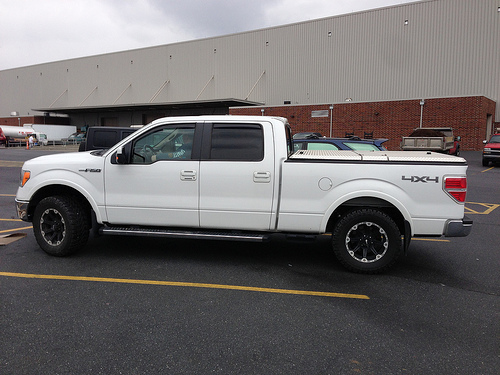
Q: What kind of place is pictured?
A: It is a road.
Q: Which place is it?
A: It is a road.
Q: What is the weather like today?
A: It is cloudy.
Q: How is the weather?
A: It is cloudy.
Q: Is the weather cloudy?
A: Yes, it is cloudy.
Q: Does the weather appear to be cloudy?
A: Yes, it is cloudy.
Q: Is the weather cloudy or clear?
A: It is cloudy.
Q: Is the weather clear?
A: No, it is cloudy.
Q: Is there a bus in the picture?
A: No, there are no buses.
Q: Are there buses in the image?
A: No, there are no buses.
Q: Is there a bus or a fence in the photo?
A: No, there are no buses or fences.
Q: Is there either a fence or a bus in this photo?
A: No, there are no buses or fences.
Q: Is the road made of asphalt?
A: Yes, the road is made of asphalt.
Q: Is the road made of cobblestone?
A: No, the road is made of asphalt.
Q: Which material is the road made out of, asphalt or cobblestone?
A: The road is made of asphalt.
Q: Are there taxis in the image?
A: Yes, there is a taxi.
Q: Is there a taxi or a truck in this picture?
A: Yes, there is a taxi.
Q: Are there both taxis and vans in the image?
A: No, there is a taxi but no vans.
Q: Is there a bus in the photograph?
A: No, there are no buses.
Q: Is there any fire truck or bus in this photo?
A: No, there are no buses or fire trucks.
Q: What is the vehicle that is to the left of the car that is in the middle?
A: The vehicle is a taxi.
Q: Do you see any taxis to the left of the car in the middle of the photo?
A: Yes, there is a taxi to the left of the car.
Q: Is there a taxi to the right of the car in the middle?
A: No, the taxi is to the left of the car.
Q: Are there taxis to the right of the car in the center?
A: No, the taxi is to the left of the car.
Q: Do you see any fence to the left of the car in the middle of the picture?
A: No, there is a taxi to the left of the car.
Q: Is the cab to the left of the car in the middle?
A: Yes, the cab is to the left of the car.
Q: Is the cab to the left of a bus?
A: No, the cab is to the left of the car.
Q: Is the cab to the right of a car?
A: No, the cab is to the left of a car.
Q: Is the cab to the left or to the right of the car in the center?
A: The cab is to the left of the car.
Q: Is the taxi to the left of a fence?
A: No, the taxi is to the left of the car.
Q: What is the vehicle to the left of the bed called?
A: The vehicle is a taxi.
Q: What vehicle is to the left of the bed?
A: The vehicle is a taxi.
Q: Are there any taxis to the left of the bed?
A: Yes, there is a taxi to the left of the bed.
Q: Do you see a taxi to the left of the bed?
A: Yes, there is a taxi to the left of the bed.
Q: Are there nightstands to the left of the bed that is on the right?
A: No, there is a taxi to the left of the bed.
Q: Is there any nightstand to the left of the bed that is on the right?
A: No, there is a taxi to the left of the bed.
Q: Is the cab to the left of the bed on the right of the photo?
A: Yes, the cab is to the left of the bed.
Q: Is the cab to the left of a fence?
A: No, the cab is to the left of the bed.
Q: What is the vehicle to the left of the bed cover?
A: The vehicle is a taxi.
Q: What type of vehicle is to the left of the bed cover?
A: The vehicle is a taxi.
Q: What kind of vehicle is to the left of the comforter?
A: The vehicle is a taxi.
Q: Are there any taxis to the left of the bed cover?
A: Yes, there is a taxi to the left of the bed cover.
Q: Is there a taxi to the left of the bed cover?
A: Yes, there is a taxi to the left of the bed cover.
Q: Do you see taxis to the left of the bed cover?
A: Yes, there is a taxi to the left of the bed cover.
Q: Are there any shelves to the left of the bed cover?
A: No, there is a taxi to the left of the bed cover.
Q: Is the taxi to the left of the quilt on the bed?
A: Yes, the taxi is to the left of the comforter.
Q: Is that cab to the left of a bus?
A: No, the cab is to the left of the comforter.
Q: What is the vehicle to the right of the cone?
A: The vehicle is a taxi.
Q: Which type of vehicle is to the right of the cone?
A: The vehicle is a taxi.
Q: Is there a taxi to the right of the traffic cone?
A: Yes, there is a taxi to the right of the traffic cone.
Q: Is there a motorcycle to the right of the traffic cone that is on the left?
A: No, there is a taxi to the right of the cone.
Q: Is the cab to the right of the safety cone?
A: Yes, the cab is to the right of the safety cone.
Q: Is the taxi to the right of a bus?
A: No, the taxi is to the right of the safety cone.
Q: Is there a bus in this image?
A: No, there are no buses.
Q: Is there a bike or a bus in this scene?
A: No, there are no buses or bikes.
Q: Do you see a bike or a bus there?
A: No, there are no buses or bikes.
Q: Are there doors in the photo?
A: Yes, there is a door.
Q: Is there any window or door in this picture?
A: Yes, there is a door.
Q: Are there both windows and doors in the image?
A: Yes, there are both a door and a window.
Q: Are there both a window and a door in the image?
A: Yes, there are both a door and a window.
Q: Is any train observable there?
A: No, there are no trains.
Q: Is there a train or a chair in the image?
A: No, there are no trains or chairs.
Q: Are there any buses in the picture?
A: No, there are no buses.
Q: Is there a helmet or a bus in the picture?
A: No, there are no buses or helmets.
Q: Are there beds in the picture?
A: Yes, there is a bed.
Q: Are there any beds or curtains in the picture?
A: Yes, there is a bed.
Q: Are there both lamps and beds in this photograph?
A: No, there is a bed but no lamps.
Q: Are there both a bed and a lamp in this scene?
A: No, there is a bed but no lamps.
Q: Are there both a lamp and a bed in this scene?
A: No, there is a bed but no lamps.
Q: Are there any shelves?
A: No, there are no shelves.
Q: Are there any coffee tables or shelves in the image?
A: No, there are no shelves or coffee tables.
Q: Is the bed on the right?
A: Yes, the bed is on the right of the image.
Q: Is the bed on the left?
A: No, the bed is on the right of the image.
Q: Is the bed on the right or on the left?
A: The bed is on the right of the image.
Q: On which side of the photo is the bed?
A: The bed is on the right of the image.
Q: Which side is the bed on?
A: The bed is on the right of the image.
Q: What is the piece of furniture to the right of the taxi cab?
A: The piece of furniture is a bed.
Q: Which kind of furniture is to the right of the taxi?
A: The piece of furniture is a bed.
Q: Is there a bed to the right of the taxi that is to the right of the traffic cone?
A: Yes, there is a bed to the right of the cab.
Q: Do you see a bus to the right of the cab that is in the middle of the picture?
A: No, there is a bed to the right of the taxi.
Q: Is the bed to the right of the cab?
A: Yes, the bed is to the right of the cab.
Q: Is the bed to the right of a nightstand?
A: No, the bed is to the right of the cab.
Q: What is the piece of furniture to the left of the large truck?
A: The piece of furniture is a bed.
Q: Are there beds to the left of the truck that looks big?
A: Yes, there is a bed to the left of the truck.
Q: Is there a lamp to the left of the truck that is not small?
A: No, there is a bed to the left of the truck.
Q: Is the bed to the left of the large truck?
A: Yes, the bed is to the left of the truck.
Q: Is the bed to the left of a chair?
A: No, the bed is to the left of the truck.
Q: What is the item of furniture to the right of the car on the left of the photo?
A: The piece of furniture is a bed.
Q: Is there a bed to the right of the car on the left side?
A: Yes, there is a bed to the right of the car.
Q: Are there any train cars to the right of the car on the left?
A: No, there is a bed to the right of the car.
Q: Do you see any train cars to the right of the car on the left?
A: No, there is a bed to the right of the car.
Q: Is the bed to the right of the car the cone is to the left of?
A: Yes, the bed is to the right of the car.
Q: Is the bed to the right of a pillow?
A: No, the bed is to the right of the car.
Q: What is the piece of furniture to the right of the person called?
A: The piece of furniture is a bed.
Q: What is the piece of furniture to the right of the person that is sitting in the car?
A: The piece of furniture is a bed.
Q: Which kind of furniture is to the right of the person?
A: The piece of furniture is a bed.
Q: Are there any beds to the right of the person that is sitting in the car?
A: Yes, there is a bed to the right of the person.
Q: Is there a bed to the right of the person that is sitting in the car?
A: Yes, there is a bed to the right of the person.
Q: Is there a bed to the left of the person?
A: No, the bed is to the right of the person.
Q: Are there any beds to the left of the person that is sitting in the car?
A: No, the bed is to the right of the person.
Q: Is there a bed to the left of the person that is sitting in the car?
A: No, the bed is to the right of the person.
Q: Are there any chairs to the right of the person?
A: No, there is a bed to the right of the person.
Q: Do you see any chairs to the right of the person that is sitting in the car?
A: No, there is a bed to the right of the person.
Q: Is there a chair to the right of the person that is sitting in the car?
A: No, there is a bed to the right of the person.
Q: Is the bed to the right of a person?
A: Yes, the bed is to the right of a person.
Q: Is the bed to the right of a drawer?
A: No, the bed is to the right of a person.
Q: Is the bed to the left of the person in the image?
A: No, the bed is to the right of the person.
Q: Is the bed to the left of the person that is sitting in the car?
A: No, the bed is to the right of the person.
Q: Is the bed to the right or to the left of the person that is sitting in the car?
A: The bed is to the right of the person.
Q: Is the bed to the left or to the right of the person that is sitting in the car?
A: The bed is to the right of the person.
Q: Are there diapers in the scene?
A: No, there are no diapers.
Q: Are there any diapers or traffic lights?
A: No, there are no diapers or traffic lights.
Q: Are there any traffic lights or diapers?
A: No, there are no diapers or traffic lights.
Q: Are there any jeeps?
A: No, there are no jeeps.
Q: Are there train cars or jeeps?
A: No, there are no jeeps or train cars.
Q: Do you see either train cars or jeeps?
A: No, there are no jeeps or train cars.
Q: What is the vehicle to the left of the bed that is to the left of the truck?
A: The vehicle is a car.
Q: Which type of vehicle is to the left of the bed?
A: The vehicle is a car.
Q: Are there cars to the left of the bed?
A: Yes, there is a car to the left of the bed.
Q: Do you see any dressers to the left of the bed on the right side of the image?
A: No, there is a car to the left of the bed.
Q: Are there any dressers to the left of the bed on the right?
A: No, there is a car to the left of the bed.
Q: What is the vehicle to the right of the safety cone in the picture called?
A: The vehicle is a car.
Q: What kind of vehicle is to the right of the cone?
A: The vehicle is a car.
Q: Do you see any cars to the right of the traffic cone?
A: Yes, there is a car to the right of the traffic cone.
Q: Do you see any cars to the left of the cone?
A: No, the car is to the right of the cone.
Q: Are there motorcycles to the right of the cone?
A: No, there is a car to the right of the cone.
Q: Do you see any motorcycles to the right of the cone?
A: No, there is a car to the right of the cone.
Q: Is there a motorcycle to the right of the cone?
A: No, there is a car to the right of the cone.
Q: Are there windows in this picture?
A: Yes, there is a window.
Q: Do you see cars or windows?
A: Yes, there is a window.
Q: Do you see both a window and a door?
A: Yes, there are both a window and a door.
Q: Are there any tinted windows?
A: Yes, there is a tinted window.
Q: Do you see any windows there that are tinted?
A: Yes, there is a window that is tinted.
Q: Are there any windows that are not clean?
A: Yes, there is a tinted window.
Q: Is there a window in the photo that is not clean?
A: Yes, there is a tinted window.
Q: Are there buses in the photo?
A: No, there are no buses.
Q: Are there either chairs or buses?
A: No, there are no buses or chairs.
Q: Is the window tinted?
A: Yes, the window is tinted.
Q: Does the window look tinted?
A: Yes, the window is tinted.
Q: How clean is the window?
A: The window is tinted.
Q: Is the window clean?
A: No, the window is tinted.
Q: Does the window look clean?
A: No, the window is tinted.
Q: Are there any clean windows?
A: No, there is a window but it is tinted.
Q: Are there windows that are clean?
A: No, there is a window but it is tinted.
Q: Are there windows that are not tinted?
A: No, there is a window but it is tinted.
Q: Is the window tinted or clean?
A: The window is tinted.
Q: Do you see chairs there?
A: No, there are no chairs.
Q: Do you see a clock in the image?
A: No, there are no clocks.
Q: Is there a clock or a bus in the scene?
A: No, there are no clocks or buses.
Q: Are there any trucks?
A: Yes, there is a truck.